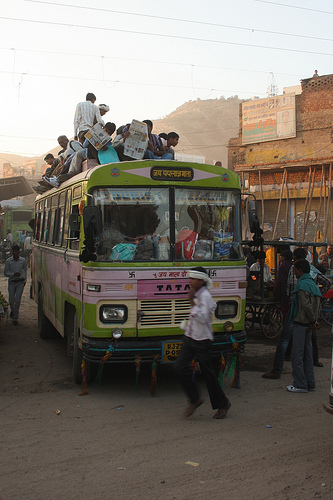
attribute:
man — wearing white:
[185, 267, 230, 420]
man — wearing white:
[75, 91, 104, 155]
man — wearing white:
[56, 134, 80, 163]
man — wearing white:
[3, 244, 28, 325]